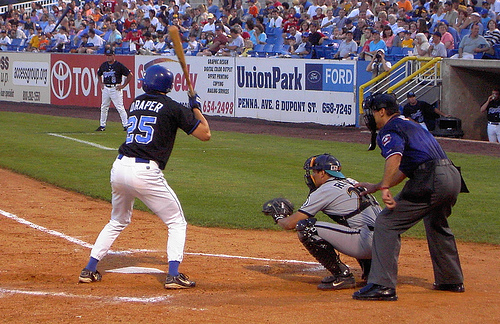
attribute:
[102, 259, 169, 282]
plate — white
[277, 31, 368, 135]
board — white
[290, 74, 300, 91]
letter — blue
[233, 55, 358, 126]
board — white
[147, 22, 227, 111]
bat — wooden, baseball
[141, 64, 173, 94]
helmet — blue, batter's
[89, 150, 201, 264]
pants — white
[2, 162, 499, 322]
ground — brown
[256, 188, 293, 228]
mitt — baseball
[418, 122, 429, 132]
pants — white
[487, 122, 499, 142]
pants — white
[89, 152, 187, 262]
pants — white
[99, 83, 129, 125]
pants — white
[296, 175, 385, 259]
uniform — gray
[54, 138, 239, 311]
pants — white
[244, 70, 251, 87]
letter — blue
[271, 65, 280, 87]
letter — blue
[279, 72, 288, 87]
letter — blue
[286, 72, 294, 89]
letter — blue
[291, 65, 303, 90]
letter — blue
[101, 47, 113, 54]
cap — black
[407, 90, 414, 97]
cap — black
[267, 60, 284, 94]
letter — blue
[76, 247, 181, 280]
socks — blue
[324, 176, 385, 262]
back — catcher's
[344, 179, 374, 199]
hand — umpire's